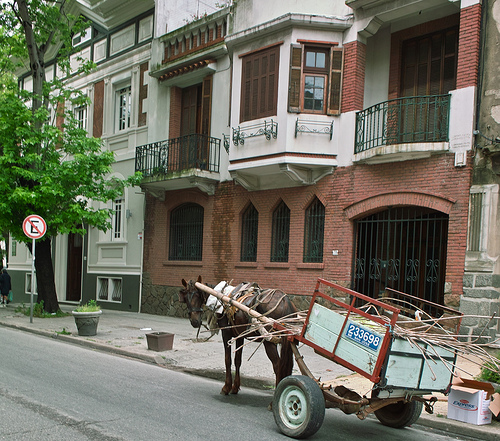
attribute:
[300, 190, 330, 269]
window — pointed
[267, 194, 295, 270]
window — pointed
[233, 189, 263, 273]
window — pointed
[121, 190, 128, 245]
frame — white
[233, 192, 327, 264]
window coverings — iron, decorative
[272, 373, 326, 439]
black tire — round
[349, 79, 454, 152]
balcony — of a building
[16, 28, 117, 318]
tree — medium sized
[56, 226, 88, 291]
door — brown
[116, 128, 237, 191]
balcony — metal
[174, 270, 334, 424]
horse — brown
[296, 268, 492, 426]
cart — wooden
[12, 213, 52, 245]
directional sign — red, white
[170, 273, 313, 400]
horse — brown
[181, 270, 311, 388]
horse — brown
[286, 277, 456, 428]
cart — left side, small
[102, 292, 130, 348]
walk — side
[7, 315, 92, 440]
street — right side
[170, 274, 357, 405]
horse — standing 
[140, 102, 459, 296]
building — red, brick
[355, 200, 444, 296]
doors — gated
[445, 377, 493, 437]
box — opened, white, sitting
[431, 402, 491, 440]
walk — side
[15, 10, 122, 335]
tree — tall, green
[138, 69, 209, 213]
terrace — small, gated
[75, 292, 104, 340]
planter — Beige , sitting 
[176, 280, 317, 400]
horse — waiting 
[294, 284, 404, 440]
cart — White , full 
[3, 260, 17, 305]
person — standing 